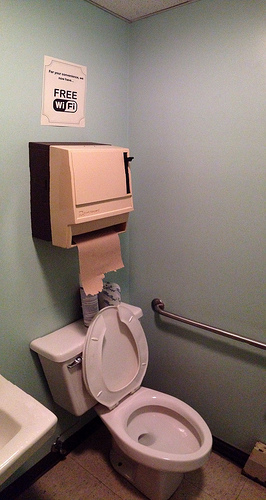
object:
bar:
[150, 297, 265, 350]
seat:
[82, 304, 150, 413]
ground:
[203, 79, 240, 115]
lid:
[83, 304, 150, 412]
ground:
[172, 126, 191, 149]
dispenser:
[28, 140, 133, 247]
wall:
[0, 0, 131, 490]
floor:
[0, 400, 265, 500]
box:
[241, 440, 266, 487]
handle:
[66, 356, 82, 372]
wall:
[134, 0, 264, 468]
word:
[52, 87, 78, 114]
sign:
[40, 55, 86, 129]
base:
[104, 437, 186, 497]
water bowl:
[28, 299, 144, 416]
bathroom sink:
[0, 369, 58, 483]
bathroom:
[0, 0, 266, 500]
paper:
[77, 233, 125, 298]